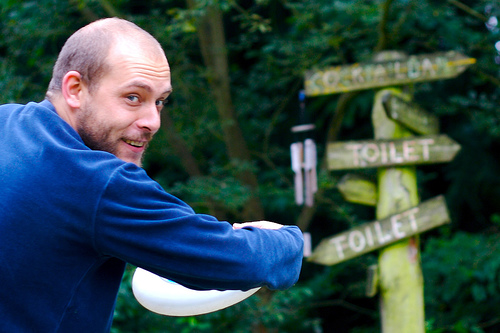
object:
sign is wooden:
[300, 49, 477, 99]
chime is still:
[289, 141, 306, 205]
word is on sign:
[308, 193, 450, 268]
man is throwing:
[0, 16, 306, 333]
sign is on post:
[324, 134, 463, 174]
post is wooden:
[373, 46, 425, 333]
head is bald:
[45, 16, 174, 174]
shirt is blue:
[0, 102, 304, 332]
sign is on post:
[305, 190, 452, 267]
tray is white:
[131, 219, 263, 316]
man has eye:
[121, 91, 142, 105]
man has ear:
[61, 69, 84, 107]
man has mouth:
[118, 136, 149, 154]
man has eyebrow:
[121, 79, 153, 91]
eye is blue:
[155, 98, 166, 108]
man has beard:
[74, 92, 142, 172]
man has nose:
[137, 96, 161, 133]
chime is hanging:
[304, 136, 319, 208]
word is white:
[345, 138, 435, 165]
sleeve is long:
[89, 162, 304, 291]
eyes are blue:
[122, 92, 167, 107]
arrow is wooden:
[380, 92, 440, 139]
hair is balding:
[42, 16, 173, 103]